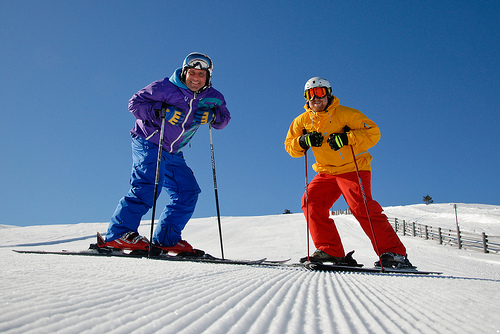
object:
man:
[283, 76, 412, 267]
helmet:
[303, 76, 331, 92]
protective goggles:
[303, 86, 329, 100]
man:
[105, 51, 231, 257]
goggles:
[185, 53, 215, 68]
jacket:
[284, 95, 381, 174]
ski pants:
[300, 167, 406, 257]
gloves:
[300, 132, 325, 146]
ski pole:
[349, 143, 383, 271]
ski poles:
[149, 102, 165, 258]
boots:
[300, 249, 357, 264]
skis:
[374, 252, 419, 269]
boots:
[97, 227, 156, 252]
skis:
[150, 239, 205, 255]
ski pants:
[105, 136, 201, 241]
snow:
[0, 201, 499, 332]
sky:
[0, 0, 500, 215]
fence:
[386, 214, 500, 254]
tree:
[422, 192, 432, 204]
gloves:
[163, 107, 187, 125]